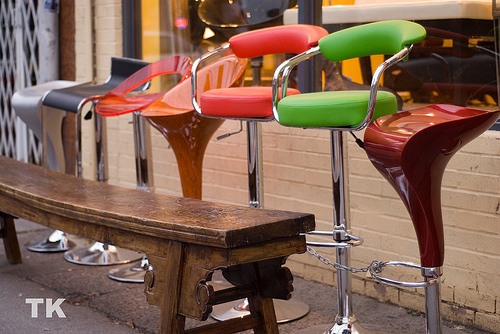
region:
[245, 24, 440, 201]
chair is green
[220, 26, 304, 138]
chair is red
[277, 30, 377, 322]
green chair has chrome stem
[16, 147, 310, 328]
brown and wooden bench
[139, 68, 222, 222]
orange and glass chair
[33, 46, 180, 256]
black and chrome chair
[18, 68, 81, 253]
steel silver chair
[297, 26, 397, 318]
chair has green cushion for back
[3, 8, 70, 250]
gate is painted white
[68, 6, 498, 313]
wall is white and brick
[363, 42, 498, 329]
a red chrome stool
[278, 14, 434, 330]
a green chrome stool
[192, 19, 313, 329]
a red chrome stool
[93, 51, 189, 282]
a red chrome stool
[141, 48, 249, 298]
a tall orange stool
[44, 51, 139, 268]
a black chrome stool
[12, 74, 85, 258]
a tall chrome stool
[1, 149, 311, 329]
a long wooden bench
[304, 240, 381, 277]
a chain link connector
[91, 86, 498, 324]
a beige painted brick wall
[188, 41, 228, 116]
a chrome arm rest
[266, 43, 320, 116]
a chrome arm rest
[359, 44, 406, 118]
a chrome arm rest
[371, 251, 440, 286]
a chrome foot rest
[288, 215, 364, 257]
a chrome foot rest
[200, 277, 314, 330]
a round chrome base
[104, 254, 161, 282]
a round chrome base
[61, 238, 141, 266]
a round chrome base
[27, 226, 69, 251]
a round chrome base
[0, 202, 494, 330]
a brick paved city sidewalk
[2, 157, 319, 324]
a wooden bench on a sidewalk outside a store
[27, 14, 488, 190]
an assortment of bar stools on the sidewalk outside a store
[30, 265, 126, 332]
an old concrete sidewalk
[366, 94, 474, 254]
a short backless barstool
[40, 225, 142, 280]
the barstools have metal bases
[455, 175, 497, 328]
the wall of the store needs to be repainted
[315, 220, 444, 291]
the barstools are chained together to prevent theft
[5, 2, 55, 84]
a secure collapsible storefront cover found in some neighborhoods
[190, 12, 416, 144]
two barstools that are the same except one is orange and the other is green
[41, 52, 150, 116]
this black barstool curves like a scroll of paper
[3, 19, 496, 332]
seven different colour barstools outside a furniture shop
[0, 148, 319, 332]
seven differently shaped barstools behind a weathered wooden bench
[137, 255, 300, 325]
wooden bench has handcut curlicue designs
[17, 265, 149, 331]
cracks in the gravel beneath the table, in front of the barstools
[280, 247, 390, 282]
chai8n securing barstool to table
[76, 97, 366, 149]
several handles for changing barstools' heights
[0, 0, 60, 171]
white iron folding gate @ left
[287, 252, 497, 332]
grime, grunge, dit, schmutz @ bottom of cream color painted bricks behind barstools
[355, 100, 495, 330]
flat seated, backless post-memphis barstool w/ silvertone round pole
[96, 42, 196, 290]
circular acrylic/lucite red barstool, minimal back, hole in centre, on shiny silvertone pole